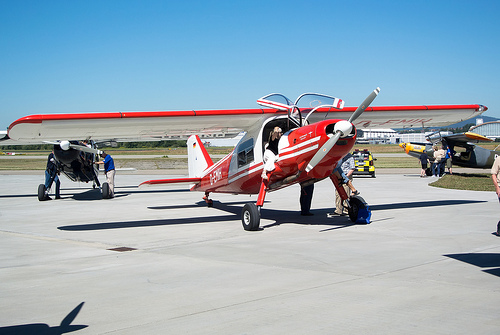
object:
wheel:
[237, 200, 267, 232]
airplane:
[6, 89, 490, 234]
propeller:
[255, 84, 385, 177]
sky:
[0, 0, 498, 123]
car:
[339, 144, 382, 181]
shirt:
[95, 154, 119, 175]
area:
[0, 164, 499, 334]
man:
[87, 149, 133, 202]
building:
[355, 127, 433, 147]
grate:
[102, 240, 146, 256]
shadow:
[55, 211, 261, 234]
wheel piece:
[348, 195, 374, 226]